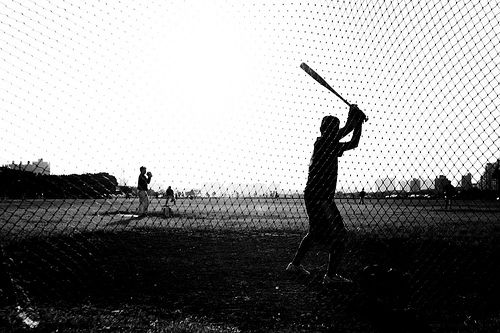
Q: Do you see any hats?
A: Yes, there is a hat.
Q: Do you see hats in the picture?
A: Yes, there is a hat.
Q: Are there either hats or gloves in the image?
A: Yes, there is a hat.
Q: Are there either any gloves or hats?
A: Yes, there is a hat.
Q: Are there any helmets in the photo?
A: No, there are no helmets.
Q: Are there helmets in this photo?
A: No, there are no helmets.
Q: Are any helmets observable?
A: No, there are no helmets.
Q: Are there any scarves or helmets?
A: No, there are no helmets or scarves.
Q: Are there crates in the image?
A: No, there are no crates.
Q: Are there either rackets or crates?
A: No, there are no crates or rackets.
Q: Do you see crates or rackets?
A: No, there are no crates or rackets.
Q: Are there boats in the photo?
A: No, there are no boats.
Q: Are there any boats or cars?
A: No, there are no boats or cars.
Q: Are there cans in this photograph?
A: No, there are no cans.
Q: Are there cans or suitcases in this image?
A: No, there are no cans or suitcases.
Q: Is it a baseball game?
A: Yes, this is a baseball game.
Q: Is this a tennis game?
A: No, this is a baseball game.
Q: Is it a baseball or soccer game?
A: This is a baseball game.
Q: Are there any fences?
A: Yes, there is a fence.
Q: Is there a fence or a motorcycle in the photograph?
A: Yes, there is a fence.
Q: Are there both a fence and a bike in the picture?
A: No, there is a fence but no bikes.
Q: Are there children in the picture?
A: Yes, there is a child.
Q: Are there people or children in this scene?
A: Yes, there is a child.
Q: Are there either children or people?
A: Yes, there is a child.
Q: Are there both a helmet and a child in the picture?
A: No, there is a child but no helmets.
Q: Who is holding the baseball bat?
A: The kid is holding the baseball bat.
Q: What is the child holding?
A: The child is holding the baseball bat.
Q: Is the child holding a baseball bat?
A: Yes, the child is holding a baseball bat.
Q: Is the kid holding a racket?
A: No, the kid is holding a baseball bat.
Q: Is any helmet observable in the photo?
A: No, there are no helmets.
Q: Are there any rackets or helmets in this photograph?
A: No, there are no helmets or rackets.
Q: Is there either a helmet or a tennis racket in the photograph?
A: No, there are no helmets or rackets.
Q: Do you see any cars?
A: No, there are no cars.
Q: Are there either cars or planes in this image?
A: No, there are no cars or planes.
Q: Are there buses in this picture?
A: No, there are no buses.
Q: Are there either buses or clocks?
A: No, there are no buses or clocks.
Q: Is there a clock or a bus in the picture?
A: No, there are no buses or clocks.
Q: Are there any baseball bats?
A: Yes, there is a baseball bat.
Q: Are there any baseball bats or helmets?
A: Yes, there is a baseball bat.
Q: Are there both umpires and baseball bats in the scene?
A: No, there is a baseball bat but no umpires.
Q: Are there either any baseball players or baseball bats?
A: Yes, there is a baseball baseball bat.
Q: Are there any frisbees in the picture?
A: No, there are no frisbees.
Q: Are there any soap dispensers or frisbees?
A: No, there are no frisbees or soap dispensers.